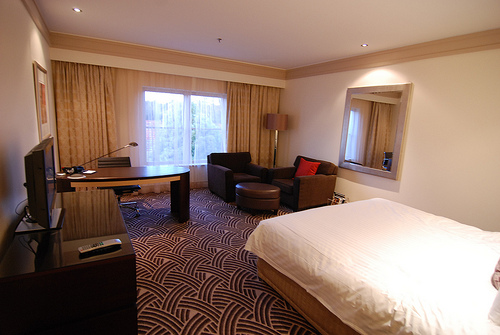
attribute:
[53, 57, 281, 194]
curtains — light brown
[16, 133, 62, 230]
tv — flat-screen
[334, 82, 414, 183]
mirror — silver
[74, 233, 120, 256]
remote — silver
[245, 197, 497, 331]
sheet — white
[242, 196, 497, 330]
bedding — white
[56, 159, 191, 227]
desk — brown